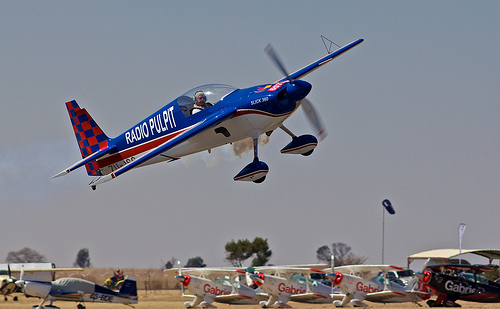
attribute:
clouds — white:
[64, 23, 199, 73]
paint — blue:
[175, 109, 185, 120]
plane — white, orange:
[162, 265, 265, 305]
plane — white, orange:
[252, 261, 329, 306]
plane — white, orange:
[319, 259, 430, 302]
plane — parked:
[84, 44, 371, 205]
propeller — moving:
[245, 30, 341, 152]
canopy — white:
[412, 247, 488, 270]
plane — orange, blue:
[51, 35, 366, 188]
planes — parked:
[51, 33, 368, 193]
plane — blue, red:
[18, 33, 407, 203]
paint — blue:
[170, 126, 204, 152]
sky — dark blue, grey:
[373, 4, 497, 161]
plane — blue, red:
[81, 60, 342, 172]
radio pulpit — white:
[123, 104, 176, 145]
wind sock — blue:
[375, 187, 405, 211]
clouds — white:
[403, 95, 459, 152]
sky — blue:
[57, 2, 469, 243]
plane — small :
[51, 70, 382, 212]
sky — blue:
[416, 63, 458, 120]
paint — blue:
[305, 53, 332, 68]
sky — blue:
[400, 74, 470, 126]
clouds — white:
[2, 185, 57, 262]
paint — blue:
[216, 87, 253, 121]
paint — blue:
[232, 88, 245, 102]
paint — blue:
[233, 93, 246, 104]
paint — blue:
[226, 90, 241, 107]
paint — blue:
[232, 84, 244, 103]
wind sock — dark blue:
[379, 196, 400, 218]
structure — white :
[0, 254, 84, 294]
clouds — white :
[123, 200, 204, 260]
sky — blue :
[0, 0, 494, 263]